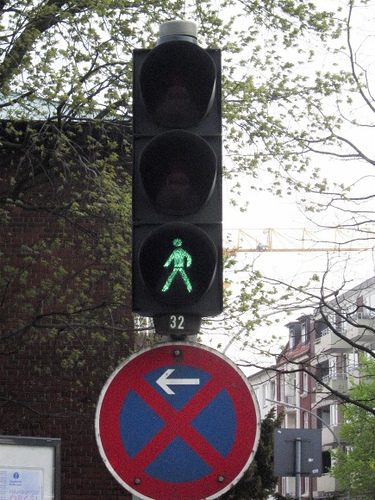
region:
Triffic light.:
[128, 38, 230, 305]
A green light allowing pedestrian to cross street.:
[139, 227, 226, 306]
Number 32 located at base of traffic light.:
[154, 304, 205, 339]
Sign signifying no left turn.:
[89, 347, 262, 498]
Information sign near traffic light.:
[0, 409, 57, 499]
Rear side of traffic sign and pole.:
[306, 430, 324, 499]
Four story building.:
[274, 291, 364, 498]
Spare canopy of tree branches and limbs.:
[248, 206, 368, 326]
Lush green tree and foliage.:
[4, 186, 94, 439]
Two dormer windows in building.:
[276, 312, 315, 348]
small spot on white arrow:
[154, 369, 177, 379]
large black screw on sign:
[155, 337, 196, 359]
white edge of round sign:
[103, 340, 145, 377]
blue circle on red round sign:
[116, 368, 236, 466]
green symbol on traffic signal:
[151, 232, 217, 300]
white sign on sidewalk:
[11, 424, 82, 489]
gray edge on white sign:
[25, 422, 66, 460]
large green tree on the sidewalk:
[330, 349, 363, 470]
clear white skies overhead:
[259, 208, 306, 231]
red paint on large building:
[261, 329, 323, 417]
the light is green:
[138, 240, 221, 312]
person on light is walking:
[146, 241, 211, 310]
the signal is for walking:
[142, 234, 215, 304]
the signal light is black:
[126, 46, 230, 329]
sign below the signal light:
[105, 49, 263, 497]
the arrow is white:
[152, 367, 202, 403]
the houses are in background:
[264, 321, 370, 487]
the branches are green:
[4, 156, 105, 401]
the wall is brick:
[29, 398, 112, 498]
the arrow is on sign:
[121, 351, 251, 495]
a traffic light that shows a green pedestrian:
[132, 20, 223, 332]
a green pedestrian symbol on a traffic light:
[158, 237, 193, 294]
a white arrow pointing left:
[156, 363, 202, 395]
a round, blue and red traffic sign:
[95, 344, 260, 498]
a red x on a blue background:
[128, 376, 224, 472]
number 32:
[165, 314, 188, 330]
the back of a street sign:
[273, 430, 317, 476]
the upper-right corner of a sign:
[0, 438, 59, 499]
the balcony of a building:
[311, 358, 344, 398]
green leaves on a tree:
[333, 350, 373, 498]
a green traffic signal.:
[124, 216, 263, 308]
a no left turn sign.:
[93, 343, 270, 498]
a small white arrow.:
[150, 357, 212, 400]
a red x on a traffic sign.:
[120, 375, 227, 480]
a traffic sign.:
[0, 430, 75, 494]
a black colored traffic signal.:
[114, 14, 254, 336]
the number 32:
[164, 308, 199, 343]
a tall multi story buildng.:
[271, 304, 308, 498]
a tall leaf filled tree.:
[0, 0, 105, 96]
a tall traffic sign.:
[264, 421, 331, 498]